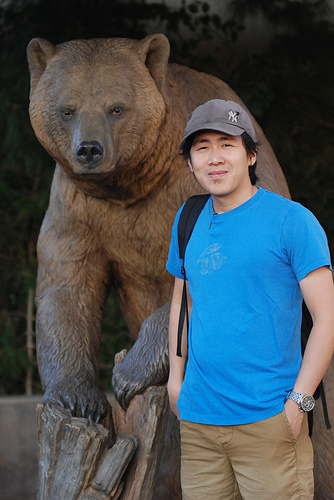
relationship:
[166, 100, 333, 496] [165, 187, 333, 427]
man wearing shirt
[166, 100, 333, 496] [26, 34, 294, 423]
man standing next to bear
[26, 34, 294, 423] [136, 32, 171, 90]
bear has right ear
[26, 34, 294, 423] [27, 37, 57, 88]
bear has left ear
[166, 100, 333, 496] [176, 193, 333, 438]
man holding backpack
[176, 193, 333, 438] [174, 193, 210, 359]
backpack has strap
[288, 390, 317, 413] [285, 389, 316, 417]
watch on right wrist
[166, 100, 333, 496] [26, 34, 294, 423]
man standing in front of bear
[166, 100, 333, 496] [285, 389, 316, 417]
man has right wrist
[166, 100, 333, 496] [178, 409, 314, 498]
man wearing pants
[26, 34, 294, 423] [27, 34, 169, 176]
bear has head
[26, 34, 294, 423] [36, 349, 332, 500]
bear has log base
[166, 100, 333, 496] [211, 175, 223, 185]
man has facial hair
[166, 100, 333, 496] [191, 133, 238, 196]
man has face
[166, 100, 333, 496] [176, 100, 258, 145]
man wearing hat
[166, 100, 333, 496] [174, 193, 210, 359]
man carrying strap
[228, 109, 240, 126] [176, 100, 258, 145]
logo on hat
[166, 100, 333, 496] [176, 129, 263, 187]
man has hair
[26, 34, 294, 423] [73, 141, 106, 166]
bear has nose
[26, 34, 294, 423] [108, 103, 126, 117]
bear has right eye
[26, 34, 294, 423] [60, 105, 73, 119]
bear has left eye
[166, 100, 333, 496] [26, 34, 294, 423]
man posing with bear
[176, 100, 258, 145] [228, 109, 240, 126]
hat has logo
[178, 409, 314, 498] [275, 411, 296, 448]
pants have pocket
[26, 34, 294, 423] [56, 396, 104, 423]
bear has claws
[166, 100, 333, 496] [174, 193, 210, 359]
man wearing strap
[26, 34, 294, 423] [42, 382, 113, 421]
bear has paw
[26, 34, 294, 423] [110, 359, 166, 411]
bear has paw